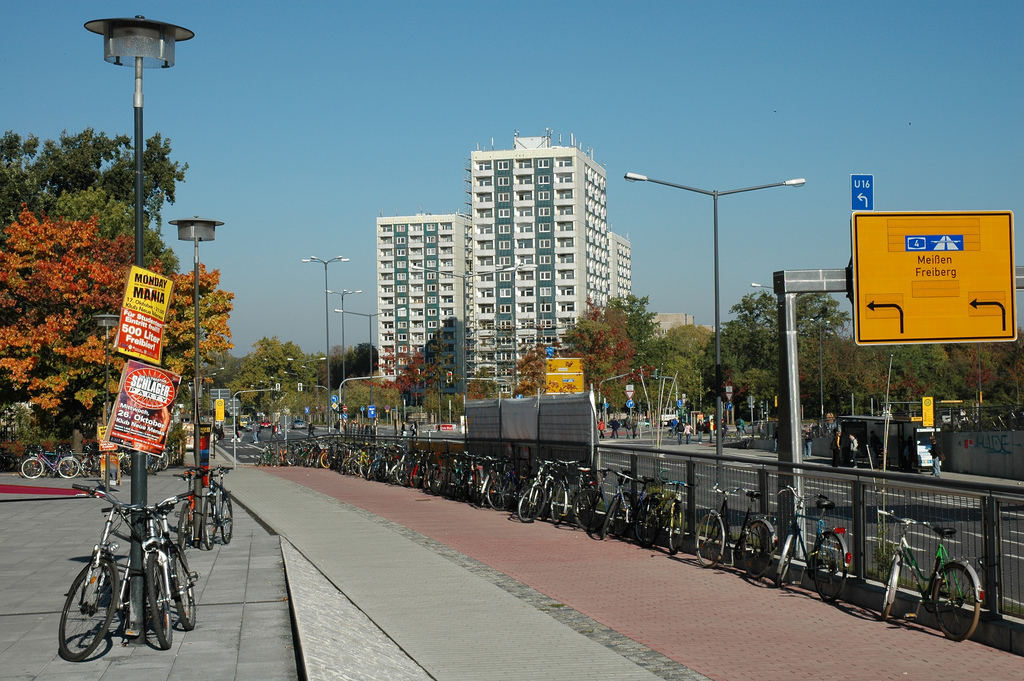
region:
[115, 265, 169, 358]
red and yellow sign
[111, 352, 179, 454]
the sign is red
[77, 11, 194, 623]
a tall light post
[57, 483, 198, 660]
the bikes are parked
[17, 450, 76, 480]
a bike is parked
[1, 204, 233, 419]
the leaves are red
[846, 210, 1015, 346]
the sign is yellow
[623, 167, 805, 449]
double headed street light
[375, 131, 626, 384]
the buildings are tall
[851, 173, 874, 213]
blue and white sign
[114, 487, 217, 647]
Bicycle leaning against a pole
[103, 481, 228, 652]
Bicycle is leaning against a pole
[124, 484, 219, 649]
Bike leaning against a pole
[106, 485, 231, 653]
Bike is leaning against a pole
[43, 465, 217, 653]
Bicycles leaning against pole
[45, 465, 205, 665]
Bicycles are leaning against a pole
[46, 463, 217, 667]
Bikes leaning against a pole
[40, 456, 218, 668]
Bikes are leaning against a pole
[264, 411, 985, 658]
Bicycles leaning against a railing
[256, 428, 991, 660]
Bicycles are leaning against a railing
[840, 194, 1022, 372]
a yellow traffic sign with blue symbols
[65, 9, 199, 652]
a saucer shaped streetlight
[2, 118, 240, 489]
a group of trees with partial fall foliage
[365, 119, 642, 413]
a cluster of tall white buildings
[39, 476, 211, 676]
a couple of bikes tied to a pole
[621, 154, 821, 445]
a streetlight with 2 lamps on it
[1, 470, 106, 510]
a sidewalkj and red painted curb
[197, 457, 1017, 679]
a sidewalk with some red pavement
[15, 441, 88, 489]
a bicycle with white tires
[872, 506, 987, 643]
green bicycle parked at the fence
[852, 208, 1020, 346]
large rectangular yellow sign above the road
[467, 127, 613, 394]
tall multi story building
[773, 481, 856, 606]
bicycle parked at the fence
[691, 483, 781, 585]
bicycle parked at the fence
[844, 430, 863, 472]
a person waiting at the bus stop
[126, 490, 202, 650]
bicycle parked at the light post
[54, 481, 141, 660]
bicycle parked at the light post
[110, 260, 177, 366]
yellow and red sign on the light post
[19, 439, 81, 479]
bicycle parked under trees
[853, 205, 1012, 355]
black and yellow sign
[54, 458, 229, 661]
bikes locked on pole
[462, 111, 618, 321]
tall white colored building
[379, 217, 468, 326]
tall white colored building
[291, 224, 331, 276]
white clouds in blue sky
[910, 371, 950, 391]
green leaves on the tree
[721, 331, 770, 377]
green leaves on the tree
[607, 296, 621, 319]
green leaves on the tree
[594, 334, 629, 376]
green leaves on the tree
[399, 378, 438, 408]
green leaves on the tree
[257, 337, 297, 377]
green leaves on the tree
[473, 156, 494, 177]
building has a window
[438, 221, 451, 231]
building has a window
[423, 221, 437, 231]
building has a window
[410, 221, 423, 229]
building has a window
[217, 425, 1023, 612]
A long dark grey road.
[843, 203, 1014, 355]
Large yellow sign to the far right.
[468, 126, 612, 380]
Closest tall white building in the background.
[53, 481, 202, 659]
Two bikes leaning on the closest pole.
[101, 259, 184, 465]
Two signs attached to the closest pole.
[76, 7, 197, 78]
Light on top of the closest pole.